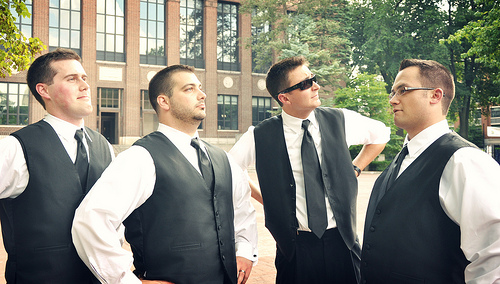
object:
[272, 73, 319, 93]
spectacle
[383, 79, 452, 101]
spectaces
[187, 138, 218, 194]
tie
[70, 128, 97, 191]
tie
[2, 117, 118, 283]
vest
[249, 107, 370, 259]
vest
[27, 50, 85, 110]
hair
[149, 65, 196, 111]
hair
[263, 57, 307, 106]
hair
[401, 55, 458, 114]
hair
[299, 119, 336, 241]
tie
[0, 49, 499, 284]
four men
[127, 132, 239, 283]
black vest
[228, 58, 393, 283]
guy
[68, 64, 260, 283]
guy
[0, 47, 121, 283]
guy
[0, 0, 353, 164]
building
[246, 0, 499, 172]
tree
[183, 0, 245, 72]
window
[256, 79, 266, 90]
white circle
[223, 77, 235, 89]
white circle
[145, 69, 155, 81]
white circle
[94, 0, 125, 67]
window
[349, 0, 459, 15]
sky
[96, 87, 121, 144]
door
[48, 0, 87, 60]
window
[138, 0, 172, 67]
window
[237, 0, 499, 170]
leaves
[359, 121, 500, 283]
shirt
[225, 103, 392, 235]
shirt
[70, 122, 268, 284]
shirt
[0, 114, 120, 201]
shirt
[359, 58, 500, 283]
man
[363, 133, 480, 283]
vests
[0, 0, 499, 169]
background